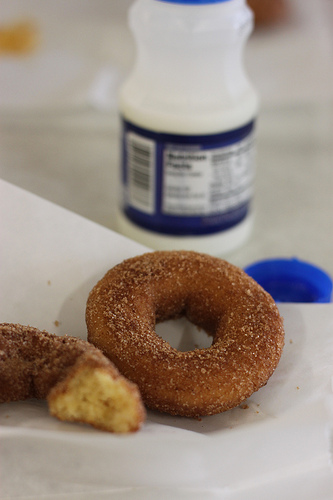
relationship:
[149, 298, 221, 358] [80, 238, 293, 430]
hole of donut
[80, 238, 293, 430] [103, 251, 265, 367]
donut with sprinkles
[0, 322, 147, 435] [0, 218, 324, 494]
donut on napkin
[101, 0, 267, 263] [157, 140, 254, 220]
bottle has nutrition facts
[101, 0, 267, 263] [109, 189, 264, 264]
bottle with some milk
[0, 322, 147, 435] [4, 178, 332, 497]
donut in box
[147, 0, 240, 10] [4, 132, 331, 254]
cap on counter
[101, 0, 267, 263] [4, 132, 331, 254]
jug on counter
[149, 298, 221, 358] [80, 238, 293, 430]
hole in doughnut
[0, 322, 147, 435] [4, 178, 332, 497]
donut on sheet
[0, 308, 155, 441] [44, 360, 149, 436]
doughnut inside yellow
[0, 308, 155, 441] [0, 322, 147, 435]
donuts half donut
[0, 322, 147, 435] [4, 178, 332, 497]
donut on paper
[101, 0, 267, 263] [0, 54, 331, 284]
bottle in table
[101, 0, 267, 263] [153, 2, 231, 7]
bottle has blue top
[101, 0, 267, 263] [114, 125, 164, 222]
bottle has price code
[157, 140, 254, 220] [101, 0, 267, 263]
ingredients listed on bottle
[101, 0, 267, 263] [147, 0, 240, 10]
bottle has blue  top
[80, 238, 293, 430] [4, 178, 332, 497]
doughnut on wax paper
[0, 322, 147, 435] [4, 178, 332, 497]
donut sitting on wax paper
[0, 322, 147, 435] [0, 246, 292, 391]
donut full of sugar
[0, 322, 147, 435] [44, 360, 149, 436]
donut inside yellow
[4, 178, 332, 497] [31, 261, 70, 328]
surface has crumbs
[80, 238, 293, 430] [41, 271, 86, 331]
doughnut has shadow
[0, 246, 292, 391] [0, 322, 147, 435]
sugar on donut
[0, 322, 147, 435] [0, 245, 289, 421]
donut has brown crust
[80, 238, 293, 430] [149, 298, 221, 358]
doughnut has hole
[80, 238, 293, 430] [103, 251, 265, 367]
doughnut has cinnamon sugar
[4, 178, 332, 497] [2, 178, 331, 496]
doughnut on waxpaper